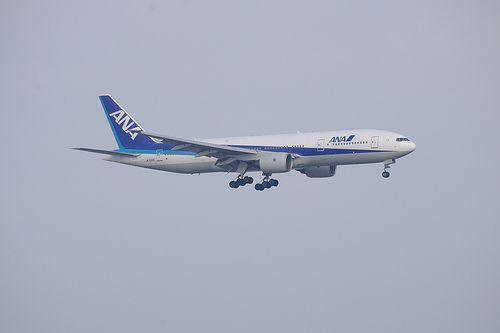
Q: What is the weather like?
A: It is cloudy.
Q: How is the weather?
A: It is cloudy.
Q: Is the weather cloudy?
A: Yes, it is cloudy.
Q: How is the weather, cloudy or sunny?
A: It is cloudy.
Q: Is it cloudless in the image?
A: No, it is cloudy.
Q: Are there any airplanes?
A: Yes, there is an airplane.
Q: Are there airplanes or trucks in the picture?
A: Yes, there is an airplane.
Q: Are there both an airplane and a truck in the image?
A: No, there is an airplane but no trucks.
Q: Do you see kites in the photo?
A: No, there are no kites.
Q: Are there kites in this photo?
A: No, there are no kites.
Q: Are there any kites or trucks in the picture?
A: No, there are no kites or trucks.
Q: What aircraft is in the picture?
A: The aircraft is an airplane.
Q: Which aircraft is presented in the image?
A: The aircraft is an airplane.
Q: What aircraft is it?
A: The aircraft is an airplane.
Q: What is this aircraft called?
A: This is an airplane.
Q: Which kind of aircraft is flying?
A: The aircraft is an airplane.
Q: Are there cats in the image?
A: No, there are no cats.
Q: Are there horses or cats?
A: No, there are no cats or horses.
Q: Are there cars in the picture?
A: No, there are no cars.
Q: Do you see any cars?
A: No, there are no cars.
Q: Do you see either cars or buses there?
A: No, there are no cars or buses.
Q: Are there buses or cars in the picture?
A: No, there are no cars or buses.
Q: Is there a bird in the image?
A: No, there are no birds.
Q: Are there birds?
A: No, there are no birds.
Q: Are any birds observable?
A: No, there are no birds.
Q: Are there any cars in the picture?
A: No, there are no cars.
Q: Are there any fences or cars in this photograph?
A: No, there are no cars or fences.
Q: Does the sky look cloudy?
A: Yes, the sky is cloudy.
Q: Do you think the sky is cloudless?
A: No, the sky is cloudy.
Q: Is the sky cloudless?
A: No, the sky is cloudy.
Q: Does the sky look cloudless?
A: No, the sky is cloudy.